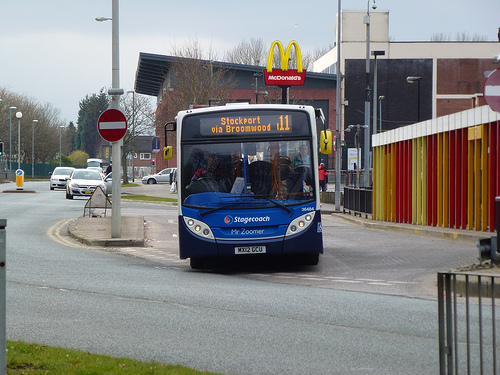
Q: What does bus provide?
A: Transportation.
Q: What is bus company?
A: Stagecoach.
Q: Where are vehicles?
A: Behind bus.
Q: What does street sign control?
A: Traffic.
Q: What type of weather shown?
A: Overcast.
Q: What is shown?
A: Information.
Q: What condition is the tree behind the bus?
A: Dead.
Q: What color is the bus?
A: Blue, grey and silver.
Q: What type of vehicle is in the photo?
A: A bus.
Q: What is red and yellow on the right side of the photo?
A: Fence slats.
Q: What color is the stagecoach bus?
A: Blue and black.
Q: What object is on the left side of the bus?
A: Light post.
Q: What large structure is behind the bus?
A: Building.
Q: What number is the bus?
A: 11.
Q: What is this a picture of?
A: Public bus.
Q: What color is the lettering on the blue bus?
A: Gold and white.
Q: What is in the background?
A: A McDonalds sign.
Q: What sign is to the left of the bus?
A: Do not enter.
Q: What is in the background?
A: Parked cars.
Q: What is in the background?
A: A large building.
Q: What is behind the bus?
A: Mcdonalds.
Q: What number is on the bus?
A: Number 11.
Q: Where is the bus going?
A: Stockport.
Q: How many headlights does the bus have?
A: 6 altogether.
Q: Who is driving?
A: The bus driver.